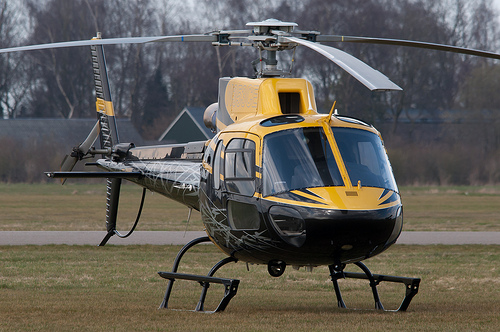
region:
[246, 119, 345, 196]
window of a hellicopter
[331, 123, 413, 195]
window of a hellicopter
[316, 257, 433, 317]
leg of a hellicopter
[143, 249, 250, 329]
leg of a hellicopter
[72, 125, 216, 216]
tail of a hellicopter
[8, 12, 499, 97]
wings of a hellicopter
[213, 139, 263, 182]
window of a hellicopter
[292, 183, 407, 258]
front of a hellicopter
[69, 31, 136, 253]
tail of a hellicopter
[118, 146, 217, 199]
back of a hellicopter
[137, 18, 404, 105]
rotors on a plane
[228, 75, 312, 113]
yellow paint on a helicopter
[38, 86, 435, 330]
helicopter on the ground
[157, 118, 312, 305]
helicopter on the ground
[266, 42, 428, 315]
helicopter on the ground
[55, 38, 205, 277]
helicopter on the ground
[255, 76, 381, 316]
helicopter on the ground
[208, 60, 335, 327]
helicopter on the ground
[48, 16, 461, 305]
yellow and black helicopter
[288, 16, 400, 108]
black sagging propeller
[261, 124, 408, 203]
shiny front windows of helicopter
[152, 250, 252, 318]
black landing gear of helicopter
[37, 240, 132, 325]
geer brown ground beneath copter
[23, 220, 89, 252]
gray pavement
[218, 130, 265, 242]
door on the side of the copter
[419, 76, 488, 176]
dark tangle of trees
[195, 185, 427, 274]
black lower body of copter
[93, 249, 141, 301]
this is a patch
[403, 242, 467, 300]
this is a patch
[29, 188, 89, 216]
this is a patch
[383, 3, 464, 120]
these branches of a tree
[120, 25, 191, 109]
these branches of a tree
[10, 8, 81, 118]
these branches of a tree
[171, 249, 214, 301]
black metal landing rail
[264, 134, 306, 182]
shiny front windshield of helicopter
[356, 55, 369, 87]
large gray helicopter propeller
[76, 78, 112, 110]
black and yellow rudder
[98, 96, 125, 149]
tail of helicopter is yellow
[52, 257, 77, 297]
grass is dry and green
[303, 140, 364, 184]
person sitting in helicopter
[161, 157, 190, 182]
helicopter with gray markings